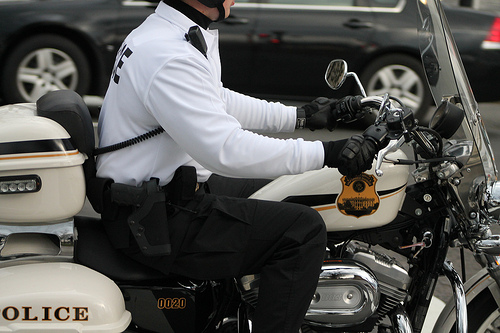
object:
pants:
[118, 183, 328, 333]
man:
[72, 0, 395, 333]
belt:
[87, 176, 220, 215]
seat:
[35, 88, 118, 214]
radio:
[187, 25, 208, 57]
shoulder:
[122, 20, 220, 84]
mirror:
[318, 55, 354, 91]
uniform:
[77, 0, 354, 332]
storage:
[1, 98, 91, 228]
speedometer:
[430, 93, 466, 136]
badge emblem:
[331, 175, 382, 221]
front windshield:
[416, 0, 498, 193]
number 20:
[170, 297, 186, 310]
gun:
[105, 177, 173, 268]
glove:
[323, 132, 378, 177]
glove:
[294, 95, 377, 131]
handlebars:
[325, 132, 386, 181]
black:
[277, 257, 320, 288]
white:
[241, 100, 271, 121]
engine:
[303, 241, 409, 331]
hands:
[324, 137, 377, 180]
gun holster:
[106, 175, 172, 267]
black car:
[0, 2, 497, 104]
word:
[0, 301, 90, 323]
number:
[179, 297, 187, 310]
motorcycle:
[0, 0, 500, 333]